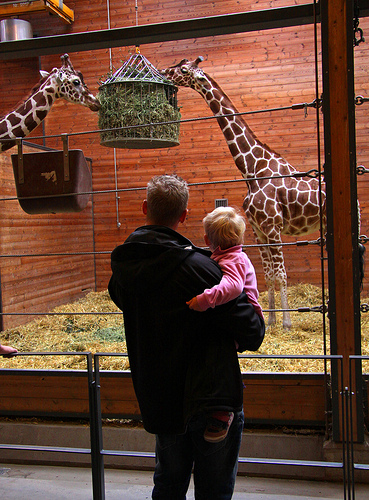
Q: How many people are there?
A: Two.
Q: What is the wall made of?
A: Wood.